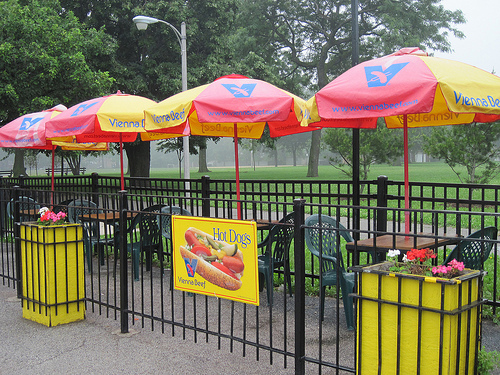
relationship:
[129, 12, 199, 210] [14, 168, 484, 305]
post standing fence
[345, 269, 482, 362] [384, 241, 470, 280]
container holding flowers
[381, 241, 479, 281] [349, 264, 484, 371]
flowers inside container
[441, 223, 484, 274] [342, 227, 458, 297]
chair pushed table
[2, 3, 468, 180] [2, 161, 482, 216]
trees growing lawn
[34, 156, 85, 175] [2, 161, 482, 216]
bench sitting lawn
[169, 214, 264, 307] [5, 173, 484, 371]
advertisement sign hanging fence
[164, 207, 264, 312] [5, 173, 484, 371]
advertisement on fence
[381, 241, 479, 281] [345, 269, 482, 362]
flowers in container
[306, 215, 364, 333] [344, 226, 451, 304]
chair at table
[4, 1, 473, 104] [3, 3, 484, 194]
foliage on trees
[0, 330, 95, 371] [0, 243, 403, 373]
cracks in paved area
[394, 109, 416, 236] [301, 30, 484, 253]
pole on umbrella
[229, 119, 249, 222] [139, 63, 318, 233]
pole on umbrella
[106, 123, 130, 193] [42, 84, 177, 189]
pole on umbrella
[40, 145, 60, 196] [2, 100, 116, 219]
pole on umbrella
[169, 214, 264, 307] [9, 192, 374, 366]
advertisement sign on gate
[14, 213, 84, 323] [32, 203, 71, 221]
container of flowers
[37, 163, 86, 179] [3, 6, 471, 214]
bench in park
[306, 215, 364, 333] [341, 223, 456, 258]
chair at table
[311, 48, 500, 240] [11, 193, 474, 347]
umbrella over table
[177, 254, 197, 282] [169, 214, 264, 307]
logo on advertisement sign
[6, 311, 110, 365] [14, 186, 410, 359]
cracks in fence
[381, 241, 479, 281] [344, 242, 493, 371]
flowers in container